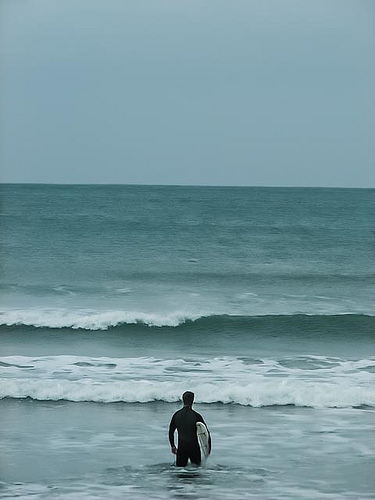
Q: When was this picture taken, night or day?
A: During the Day.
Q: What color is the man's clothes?
A: Black.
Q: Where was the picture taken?
A: At the beach.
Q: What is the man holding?
A: A surfboard.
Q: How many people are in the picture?
A: One.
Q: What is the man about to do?
A: Surf.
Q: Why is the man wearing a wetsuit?
A: The water is cold.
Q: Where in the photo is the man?
A: Bottom center.